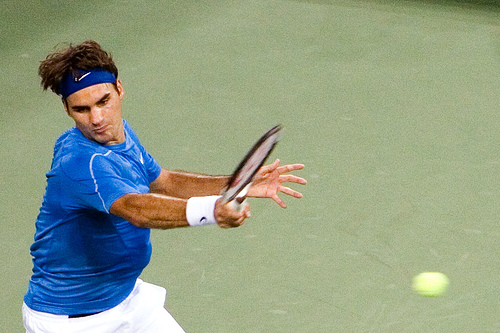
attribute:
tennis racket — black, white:
[220, 123, 283, 213]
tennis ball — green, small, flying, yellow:
[412, 271, 450, 297]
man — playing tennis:
[21, 37, 307, 333]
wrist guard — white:
[186, 193, 224, 227]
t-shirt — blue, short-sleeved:
[22, 118, 160, 317]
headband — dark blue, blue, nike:
[58, 66, 115, 99]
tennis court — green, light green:
[0, 1, 499, 333]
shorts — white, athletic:
[22, 278, 187, 333]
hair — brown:
[39, 39, 117, 95]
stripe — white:
[89, 149, 113, 215]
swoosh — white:
[74, 71, 92, 82]